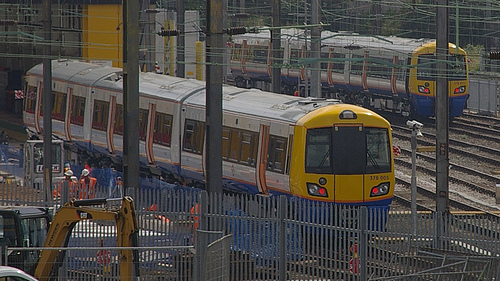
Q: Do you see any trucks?
A: No, there are no trucks.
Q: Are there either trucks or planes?
A: No, there are no trucks or planes.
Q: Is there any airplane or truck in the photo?
A: No, there are no trucks or airplanes.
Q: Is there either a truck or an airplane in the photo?
A: No, there are no trucks or airplanes.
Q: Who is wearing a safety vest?
A: The worker is wearing a safety vest.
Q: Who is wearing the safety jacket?
A: The worker is wearing a safety vest.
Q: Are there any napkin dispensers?
A: No, there are no napkin dispensers.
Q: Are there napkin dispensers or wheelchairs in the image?
A: No, there are no napkin dispensers or wheelchairs.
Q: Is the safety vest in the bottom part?
A: Yes, the safety vest is in the bottom of the image.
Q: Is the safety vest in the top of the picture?
A: No, the safety vest is in the bottom of the image.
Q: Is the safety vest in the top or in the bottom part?
A: The safety vest is in the bottom of the image.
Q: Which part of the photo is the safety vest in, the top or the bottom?
A: The safety vest is in the bottom of the image.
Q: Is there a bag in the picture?
A: No, there are no bags.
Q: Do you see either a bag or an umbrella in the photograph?
A: No, there are no bags or umbrellas.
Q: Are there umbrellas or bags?
A: No, there are no bags or umbrellas.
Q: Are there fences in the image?
A: Yes, there is a fence.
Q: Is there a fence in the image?
A: Yes, there is a fence.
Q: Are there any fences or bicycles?
A: Yes, there is a fence.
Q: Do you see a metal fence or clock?
A: Yes, there is a metal fence.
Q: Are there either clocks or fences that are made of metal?
A: Yes, the fence is made of metal.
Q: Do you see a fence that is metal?
A: Yes, there is a metal fence.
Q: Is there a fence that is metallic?
A: Yes, there is a fence that is metallic.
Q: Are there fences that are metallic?
A: Yes, there is a fence that is metallic.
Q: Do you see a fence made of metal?
A: Yes, there is a fence that is made of metal.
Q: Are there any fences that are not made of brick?
A: Yes, there is a fence that is made of metal.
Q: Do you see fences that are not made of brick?
A: Yes, there is a fence that is made of metal.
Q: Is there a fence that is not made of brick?
A: Yes, there is a fence that is made of metal.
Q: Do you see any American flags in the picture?
A: No, there are no American flags.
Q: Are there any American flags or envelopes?
A: No, there are no American flags or envelopes.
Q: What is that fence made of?
A: The fence is made of metal.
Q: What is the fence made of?
A: The fence is made of metal.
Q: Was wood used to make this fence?
A: No, the fence is made of metal.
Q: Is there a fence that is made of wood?
A: No, there is a fence but it is made of metal.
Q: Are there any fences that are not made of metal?
A: No, there is a fence but it is made of metal.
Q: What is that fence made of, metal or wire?
A: The fence is made of metal.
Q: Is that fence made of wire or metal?
A: The fence is made of metal.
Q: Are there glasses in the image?
A: No, there are no glasses.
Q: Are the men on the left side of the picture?
A: Yes, the men are on the left of the image.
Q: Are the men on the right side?
A: No, the men are on the left of the image.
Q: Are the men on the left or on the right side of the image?
A: The men are on the left of the image.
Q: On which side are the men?
A: The men are on the left of the image.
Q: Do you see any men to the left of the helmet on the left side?
A: No, the men are to the right of the helmet.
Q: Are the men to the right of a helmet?
A: Yes, the men are to the right of a helmet.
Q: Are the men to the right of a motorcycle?
A: No, the men are to the right of a helmet.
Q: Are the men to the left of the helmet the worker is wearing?
A: No, the men are to the right of the helmet.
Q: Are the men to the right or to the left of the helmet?
A: The men are to the right of the helmet.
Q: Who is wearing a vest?
A: The men are wearing a vest.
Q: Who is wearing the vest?
A: The men are wearing a vest.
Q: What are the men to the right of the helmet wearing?
A: The men are wearing a vest.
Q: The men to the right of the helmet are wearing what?
A: The men are wearing a vest.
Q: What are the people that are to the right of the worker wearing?
A: The men are wearing a vest.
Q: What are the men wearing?
A: The men are wearing a vest.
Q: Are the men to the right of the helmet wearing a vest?
A: Yes, the men are wearing a vest.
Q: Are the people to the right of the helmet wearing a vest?
A: Yes, the men are wearing a vest.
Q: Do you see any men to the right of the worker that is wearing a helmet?
A: Yes, there are men to the right of the worker.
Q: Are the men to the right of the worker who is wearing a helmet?
A: Yes, the men are to the right of the worker.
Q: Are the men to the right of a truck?
A: No, the men are to the right of the worker.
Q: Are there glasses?
A: No, there are no glasses.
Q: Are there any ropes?
A: No, there are no ropes.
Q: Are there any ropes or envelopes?
A: No, there are no ropes or envelopes.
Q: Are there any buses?
A: No, there are no buses.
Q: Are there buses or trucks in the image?
A: No, there are no buses or trucks.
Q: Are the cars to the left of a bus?
A: No, the cars are to the left of a train.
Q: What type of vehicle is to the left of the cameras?
A: The vehicles are cars.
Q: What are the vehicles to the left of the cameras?
A: The vehicles are cars.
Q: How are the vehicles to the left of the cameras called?
A: The vehicles are cars.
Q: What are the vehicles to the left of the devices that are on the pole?
A: The vehicles are cars.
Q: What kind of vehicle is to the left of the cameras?
A: The vehicles are cars.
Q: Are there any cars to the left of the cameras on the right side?
A: Yes, there are cars to the left of the cameras.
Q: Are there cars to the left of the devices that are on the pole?
A: Yes, there are cars to the left of the cameras.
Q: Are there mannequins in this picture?
A: No, there are no mannequins.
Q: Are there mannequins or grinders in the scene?
A: No, there are no mannequins or grinders.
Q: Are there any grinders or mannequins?
A: No, there are no mannequins or grinders.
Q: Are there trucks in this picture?
A: No, there are no trucks.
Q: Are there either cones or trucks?
A: No, there are no trucks or cones.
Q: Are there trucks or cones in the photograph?
A: No, there are no trucks or cones.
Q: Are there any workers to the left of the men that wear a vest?
A: Yes, there is a worker to the left of the men.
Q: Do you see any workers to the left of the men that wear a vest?
A: Yes, there is a worker to the left of the men.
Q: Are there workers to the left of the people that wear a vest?
A: Yes, there is a worker to the left of the men.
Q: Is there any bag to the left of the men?
A: No, there is a worker to the left of the men.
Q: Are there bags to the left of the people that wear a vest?
A: No, there is a worker to the left of the men.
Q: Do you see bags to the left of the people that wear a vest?
A: No, there is a worker to the left of the men.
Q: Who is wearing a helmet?
A: The worker is wearing a helmet.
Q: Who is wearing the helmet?
A: The worker is wearing a helmet.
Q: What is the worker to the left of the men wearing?
A: The worker is wearing a helmet.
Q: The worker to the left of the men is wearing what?
A: The worker is wearing a helmet.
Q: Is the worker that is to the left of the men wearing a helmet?
A: Yes, the worker is wearing a helmet.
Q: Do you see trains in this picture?
A: Yes, there is a train.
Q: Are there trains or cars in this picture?
A: Yes, there is a train.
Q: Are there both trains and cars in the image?
A: Yes, there are both a train and a car.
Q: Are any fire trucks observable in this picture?
A: No, there are no fire trucks.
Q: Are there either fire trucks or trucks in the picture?
A: No, there are no fire trucks or trucks.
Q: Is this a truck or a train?
A: This is a train.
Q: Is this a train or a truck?
A: This is a train.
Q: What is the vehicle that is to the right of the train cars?
A: The vehicle is a train.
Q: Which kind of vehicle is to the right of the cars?
A: The vehicle is a train.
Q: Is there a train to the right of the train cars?
A: Yes, there is a train to the right of the cars.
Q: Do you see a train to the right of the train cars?
A: Yes, there is a train to the right of the cars.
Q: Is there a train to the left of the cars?
A: No, the train is to the right of the cars.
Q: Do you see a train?
A: Yes, there is a train.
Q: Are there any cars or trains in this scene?
A: Yes, there is a train.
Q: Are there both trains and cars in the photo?
A: Yes, there are both a train and a car.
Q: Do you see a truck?
A: No, there are no trucks.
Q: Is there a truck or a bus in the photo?
A: No, there are no trucks or buses.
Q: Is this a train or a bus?
A: This is a train.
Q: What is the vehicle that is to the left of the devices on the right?
A: The vehicle is a train.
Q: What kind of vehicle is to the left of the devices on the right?
A: The vehicle is a train.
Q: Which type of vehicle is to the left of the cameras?
A: The vehicle is a train.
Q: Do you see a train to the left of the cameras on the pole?
A: Yes, there is a train to the left of the cameras.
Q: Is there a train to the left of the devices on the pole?
A: Yes, there is a train to the left of the cameras.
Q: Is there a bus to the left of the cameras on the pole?
A: No, there is a train to the left of the cameras.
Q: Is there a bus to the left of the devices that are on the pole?
A: No, there is a train to the left of the cameras.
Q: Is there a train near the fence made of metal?
A: Yes, there is a train near the fence.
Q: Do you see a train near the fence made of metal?
A: Yes, there is a train near the fence.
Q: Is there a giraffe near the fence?
A: No, there is a train near the fence.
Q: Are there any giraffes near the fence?
A: No, there is a train near the fence.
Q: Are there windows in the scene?
A: Yes, there are windows.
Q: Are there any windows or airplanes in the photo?
A: Yes, there are windows.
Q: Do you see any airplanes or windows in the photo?
A: Yes, there are windows.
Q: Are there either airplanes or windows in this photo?
A: Yes, there are windows.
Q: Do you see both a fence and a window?
A: Yes, there are both a window and a fence.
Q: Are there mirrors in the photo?
A: No, there are no mirrors.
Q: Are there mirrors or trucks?
A: No, there are no mirrors or trucks.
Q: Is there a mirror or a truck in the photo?
A: No, there are no mirrors or trucks.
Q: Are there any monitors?
A: No, there are no monitors.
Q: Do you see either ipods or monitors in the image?
A: No, there are no monitors or ipods.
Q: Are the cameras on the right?
A: Yes, the cameras are on the right of the image.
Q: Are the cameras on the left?
A: No, the cameras are on the right of the image.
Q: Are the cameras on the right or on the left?
A: The cameras are on the right of the image.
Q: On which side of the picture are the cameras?
A: The cameras are on the right of the image.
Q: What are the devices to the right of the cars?
A: The devices are cameras.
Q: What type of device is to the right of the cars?
A: The devices are cameras.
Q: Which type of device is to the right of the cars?
A: The devices are cameras.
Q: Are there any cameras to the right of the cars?
A: Yes, there are cameras to the right of the cars.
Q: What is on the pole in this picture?
A: The cameras are on the pole.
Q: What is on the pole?
A: The cameras are on the pole.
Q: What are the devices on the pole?
A: The devices are cameras.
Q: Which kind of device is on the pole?
A: The devices are cameras.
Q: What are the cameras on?
A: The cameras are on the pole.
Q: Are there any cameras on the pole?
A: Yes, there are cameras on the pole.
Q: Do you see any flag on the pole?
A: No, there are cameras on the pole.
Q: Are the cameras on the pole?
A: Yes, the cameras are on the pole.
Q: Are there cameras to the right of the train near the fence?
A: Yes, there are cameras to the right of the train.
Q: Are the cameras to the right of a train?
A: Yes, the cameras are to the right of a train.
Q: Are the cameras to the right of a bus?
A: No, the cameras are to the right of a train.